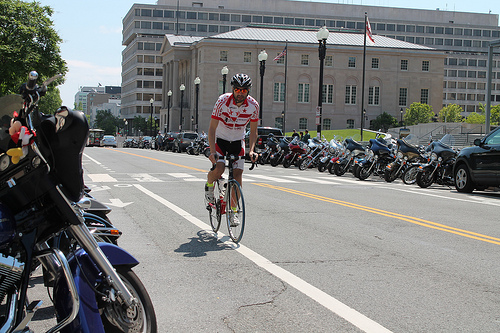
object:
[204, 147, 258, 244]
bicycle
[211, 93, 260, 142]
jersey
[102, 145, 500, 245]
yellow line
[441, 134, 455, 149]
motorcycle's windshield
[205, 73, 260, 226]
man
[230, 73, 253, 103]
helmet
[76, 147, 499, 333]
street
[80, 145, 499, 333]
road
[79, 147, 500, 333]
ground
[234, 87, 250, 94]
glasses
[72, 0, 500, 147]
buildings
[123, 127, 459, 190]
motorcycle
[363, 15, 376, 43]
flag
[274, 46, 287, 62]
flag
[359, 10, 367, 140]
post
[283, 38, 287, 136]
post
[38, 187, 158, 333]
front fork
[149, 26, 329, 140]
posts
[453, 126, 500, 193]
car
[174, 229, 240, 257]
shadow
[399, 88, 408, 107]
window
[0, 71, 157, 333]
motorcycle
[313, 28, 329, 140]
lamp post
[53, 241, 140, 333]
fender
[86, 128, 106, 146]
bus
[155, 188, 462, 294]
paved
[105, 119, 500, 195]
row